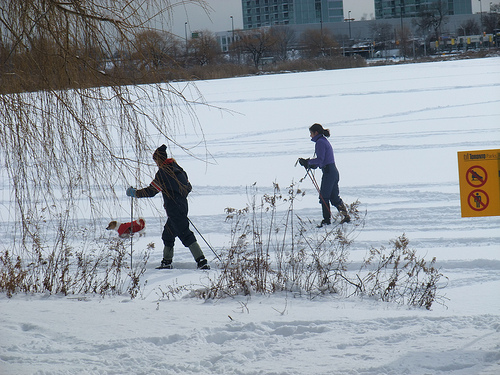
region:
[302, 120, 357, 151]
head of the girl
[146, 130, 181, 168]
face of the girl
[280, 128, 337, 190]
hand of the girl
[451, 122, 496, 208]
a signals in ice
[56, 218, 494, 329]
a beautiful view of trees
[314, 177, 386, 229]
legs of the girl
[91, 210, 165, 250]
a small dog in ice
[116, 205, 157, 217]
a small thread to hold dog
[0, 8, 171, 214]
a old dry tree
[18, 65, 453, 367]
a clear view of sky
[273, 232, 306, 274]
part of a plant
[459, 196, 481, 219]
part of a board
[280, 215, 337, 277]
part of a plant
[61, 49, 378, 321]
two people are sking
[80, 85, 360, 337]
a man, woman and dog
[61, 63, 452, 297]
they are sking on snow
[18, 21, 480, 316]
the trail is in a park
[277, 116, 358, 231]
the woman has a bun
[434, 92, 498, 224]
the warning sign is yellow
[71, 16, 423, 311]
buildings in the distance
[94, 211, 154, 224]
the dog is brown and white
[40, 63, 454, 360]
grass poking through snow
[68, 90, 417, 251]
they ski together in the park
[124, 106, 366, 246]
These are two people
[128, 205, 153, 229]
This is a dog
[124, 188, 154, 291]
The dog has an outfit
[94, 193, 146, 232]
The outfit is red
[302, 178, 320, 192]
This is a leash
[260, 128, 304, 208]
The leash is black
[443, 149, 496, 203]
This is a sign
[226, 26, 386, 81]
This is a building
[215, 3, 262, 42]
This is a street lamp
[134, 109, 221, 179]
This is a hat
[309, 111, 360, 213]
this is a lady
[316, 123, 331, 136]
this is the hair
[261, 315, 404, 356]
this is the snow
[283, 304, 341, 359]
the snow is white in color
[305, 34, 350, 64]
this is a tree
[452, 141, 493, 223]
this is a signpost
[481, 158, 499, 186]
the signpost is yellow in color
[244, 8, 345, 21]
this is a building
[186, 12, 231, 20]
this is the sky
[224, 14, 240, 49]
this is a pole